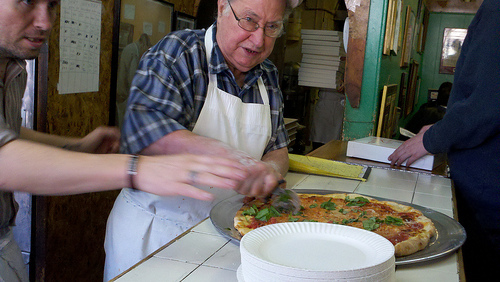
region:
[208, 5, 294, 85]
head of a person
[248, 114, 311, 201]
arm of a person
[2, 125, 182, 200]
arm of a person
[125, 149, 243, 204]
hand of a person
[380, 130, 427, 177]
hand of a person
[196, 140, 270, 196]
fingers of a person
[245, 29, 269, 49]
nose of a person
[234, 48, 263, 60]
mouth of a person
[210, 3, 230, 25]
ear of a person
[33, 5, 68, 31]
nose of a person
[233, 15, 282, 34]
glasses on man's face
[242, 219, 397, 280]
white stack of paper plates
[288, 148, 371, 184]
yellow note pad on counter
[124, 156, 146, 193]
watch on man's wrist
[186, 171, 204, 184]
ring on the man's finger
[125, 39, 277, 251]
white apron on older man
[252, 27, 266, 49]
nose of the older man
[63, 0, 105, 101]
white poster on the wall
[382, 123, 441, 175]
the man's left hand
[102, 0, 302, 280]
Elderly man cutting slices of pizza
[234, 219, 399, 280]
Stack of white paper plates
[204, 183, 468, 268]
Vegetarian pizza on a round pizza pan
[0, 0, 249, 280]
Man reaching for paper plate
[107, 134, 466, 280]
Wood and tile serving counter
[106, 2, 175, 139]
Photo of a man on back wall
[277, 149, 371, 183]
Yellow notepad on serving counter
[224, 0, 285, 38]
Eyeglasses on face of elderly man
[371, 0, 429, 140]
Group of photos on green wall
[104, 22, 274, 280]
White apron worn by elderly man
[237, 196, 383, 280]
plates are white in color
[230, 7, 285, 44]
man is wearing glasses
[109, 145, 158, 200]
man is wearing a watch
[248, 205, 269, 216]
green leaf vegetable on the pizza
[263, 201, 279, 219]
green leaf vegetable on the pizza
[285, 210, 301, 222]
green leaf vegetable on the pizza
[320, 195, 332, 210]
green leaf vegetable on the pizza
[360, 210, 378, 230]
green leaf vegetable on the pizza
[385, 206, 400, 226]
green leaf vegetable on the pizza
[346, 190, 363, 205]
green leaf vegetable on the pizza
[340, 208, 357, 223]
green leaf vegetable on the pizza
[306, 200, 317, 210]
green leaf vegetable on the pizza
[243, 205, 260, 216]
green leaf vegetable on the pizza